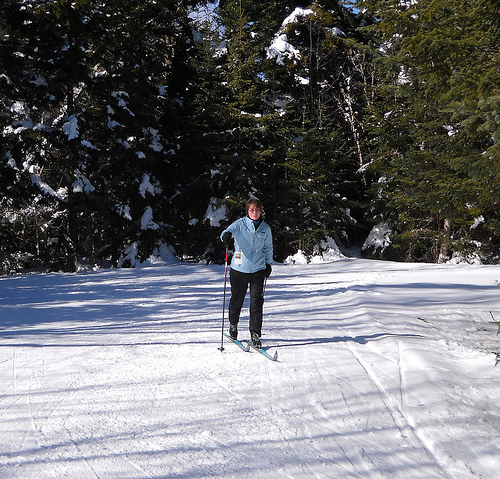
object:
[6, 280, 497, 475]
snow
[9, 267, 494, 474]
ground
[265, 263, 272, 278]
glove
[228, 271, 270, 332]
black pants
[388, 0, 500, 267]
fir trees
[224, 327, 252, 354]
her skis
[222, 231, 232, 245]
gloves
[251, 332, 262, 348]
boots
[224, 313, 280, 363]
skies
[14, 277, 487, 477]
trail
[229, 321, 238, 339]
boot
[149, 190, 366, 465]
skiing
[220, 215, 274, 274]
jacket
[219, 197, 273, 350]
person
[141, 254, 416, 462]
snow trail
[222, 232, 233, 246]
hand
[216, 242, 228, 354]
pole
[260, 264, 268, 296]
pole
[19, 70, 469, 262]
background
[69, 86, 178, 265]
snow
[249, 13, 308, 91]
snow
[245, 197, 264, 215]
hair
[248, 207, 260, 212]
glasses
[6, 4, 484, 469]
mountains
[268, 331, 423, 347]
shadow